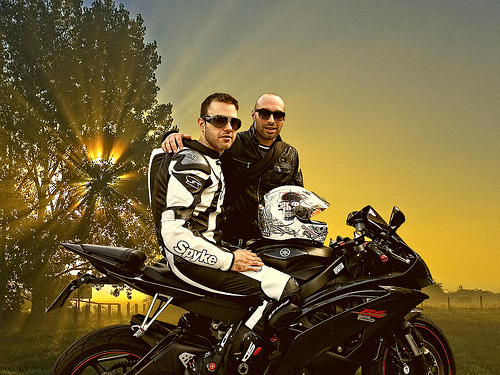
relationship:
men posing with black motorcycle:
[136, 83, 327, 375] [35, 198, 467, 374]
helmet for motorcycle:
[248, 178, 336, 254] [77, 244, 426, 350]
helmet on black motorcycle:
[250, 184, 330, 245] [35, 198, 467, 374]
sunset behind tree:
[3, 1, 499, 311] [3, 3, 182, 315]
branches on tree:
[30, 156, 58, 218] [3, 3, 182, 315]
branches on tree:
[7, 48, 41, 123] [3, 3, 182, 315]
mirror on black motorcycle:
[387, 204, 405, 229] [35, 198, 467, 374]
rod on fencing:
[446, 296, 453, 309] [424, 297, 499, 312]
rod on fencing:
[474, 293, 485, 310] [424, 297, 499, 312]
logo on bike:
[277, 244, 294, 258] [42, 213, 449, 363]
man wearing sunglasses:
[135, 88, 308, 375] [203, 112, 242, 132]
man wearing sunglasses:
[135, 88, 308, 375] [255, 106, 285, 120]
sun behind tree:
[62, 142, 143, 215] [3, 0, 188, 323]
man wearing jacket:
[226, 89, 300, 243] [224, 132, 301, 237]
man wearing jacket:
[158, 87, 302, 371] [158, 143, 228, 265]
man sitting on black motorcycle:
[135, 88, 308, 375] [35, 198, 467, 374]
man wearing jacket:
[135, 88, 308, 375] [146, 138, 235, 272]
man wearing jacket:
[158, 92, 304, 246] [221, 129, 303, 239]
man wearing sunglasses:
[135, 88, 308, 375] [197, 110, 247, 133]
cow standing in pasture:
[455, 292, 475, 307] [416, 303, 499, 372]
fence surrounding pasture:
[66, 294, 158, 326] [6, 320, 78, 368]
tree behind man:
[3, 0, 188, 323] [157, 81, 295, 288]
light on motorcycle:
[386, 204, 405, 233] [74, 232, 433, 362]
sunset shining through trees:
[3, 1, 499, 311] [19, 40, 177, 340]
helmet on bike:
[248, 178, 336, 254] [44, 205, 455, 373]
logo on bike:
[349, 304, 386, 325] [44, 205, 455, 373]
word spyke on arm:
[162, 225, 262, 271] [163, 147, 261, 271]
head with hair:
[176, 78, 250, 161] [197, 89, 242, 116]